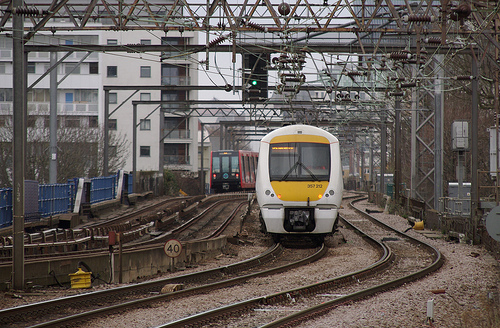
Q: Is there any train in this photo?
A: Yes, there is a train.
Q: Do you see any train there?
A: Yes, there is a train.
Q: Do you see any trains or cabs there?
A: Yes, there is a train.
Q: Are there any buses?
A: No, there are no buses.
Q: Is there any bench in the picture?
A: No, there are no benches.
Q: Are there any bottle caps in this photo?
A: No, there are no bottle caps.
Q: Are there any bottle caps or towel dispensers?
A: No, there are no bottle caps or towel dispensers.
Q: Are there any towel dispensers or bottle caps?
A: No, there are no bottle caps or towel dispensers.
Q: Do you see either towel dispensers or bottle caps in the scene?
A: No, there are no bottle caps or towel dispensers.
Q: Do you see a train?
A: Yes, there is a train.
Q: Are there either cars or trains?
A: Yes, there is a train.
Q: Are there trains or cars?
A: Yes, there is a train.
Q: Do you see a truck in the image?
A: No, there are no trucks.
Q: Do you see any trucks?
A: No, there are no trucks.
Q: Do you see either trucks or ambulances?
A: No, there are no trucks or ambulances.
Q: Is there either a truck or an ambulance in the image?
A: No, there are no trucks or ambulances.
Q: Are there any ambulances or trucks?
A: No, there are no trucks or ambulances.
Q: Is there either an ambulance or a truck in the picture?
A: No, there are no trucks or ambulances.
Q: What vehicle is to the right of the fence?
A: The vehicle is a train.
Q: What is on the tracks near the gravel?
A: The train is on the train tracks.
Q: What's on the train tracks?
A: The train is on the train tracks.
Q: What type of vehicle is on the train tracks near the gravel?
A: The vehicle is a train.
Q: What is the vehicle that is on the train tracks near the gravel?
A: The vehicle is a train.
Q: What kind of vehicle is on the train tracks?
A: The vehicle is a train.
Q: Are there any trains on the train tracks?
A: Yes, there is a train on the train tracks.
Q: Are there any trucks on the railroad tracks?
A: No, there is a train on the railroad tracks.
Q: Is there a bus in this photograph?
A: No, there are no buses.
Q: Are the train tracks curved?
A: Yes, the train tracks are curved.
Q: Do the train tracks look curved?
A: Yes, the train tracks are curved.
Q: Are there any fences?
A: Yes, there is a fence.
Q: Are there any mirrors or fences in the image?
A: Yes, there is a fence.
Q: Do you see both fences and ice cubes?
A: No, there is a fence but no ice cubes.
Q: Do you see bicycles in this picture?
A: No, there are no bicycles.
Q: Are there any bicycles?
A: No, there are no bicycles.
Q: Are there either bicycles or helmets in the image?
A: No, there are no bicycles or helmets.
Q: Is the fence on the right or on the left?
A: The fence is on the left of the image.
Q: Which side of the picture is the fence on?
A: The fence is on the left of the image.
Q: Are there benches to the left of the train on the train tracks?
A: No, there is a fence to the left of the train.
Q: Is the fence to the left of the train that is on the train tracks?
A: Yes, the fence is to the left of the train.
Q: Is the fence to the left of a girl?
A: No, the fence is to the left of the train.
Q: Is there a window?
A: Yes, there is a window.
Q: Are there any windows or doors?
A: Yes, there is a window.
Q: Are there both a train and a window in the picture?
A: Yes, there are both a window and a train.